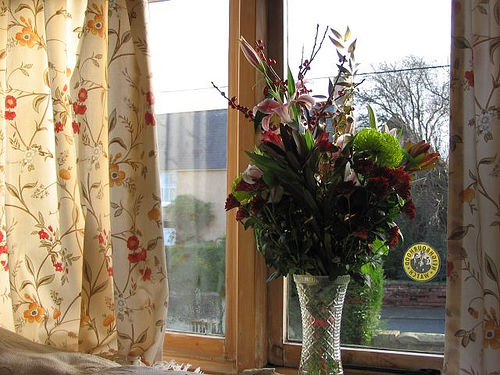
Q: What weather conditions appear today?
A: It is cloudy.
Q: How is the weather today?
A: It is cloudy.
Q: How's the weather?
A: It is cloudy.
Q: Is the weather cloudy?
A: Yes, it is cloudy.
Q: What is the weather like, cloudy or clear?
A: It is cloudy.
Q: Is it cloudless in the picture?
A: No, it is cloudy.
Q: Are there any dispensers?
A: No, there are no dispensers.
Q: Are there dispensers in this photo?
A: No, there are no dispensers.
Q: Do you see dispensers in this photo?
A: No, there are no dispensers.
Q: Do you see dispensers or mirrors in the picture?
A: No, there are no dispensers or mirrors.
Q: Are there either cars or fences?
A: No, there are no cars or fences.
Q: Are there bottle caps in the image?
A: No, there are no bottle caps.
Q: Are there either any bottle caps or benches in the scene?
A: No, there are no bottle caps or benches.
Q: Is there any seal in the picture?
A: Yes, there is a seal.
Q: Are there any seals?
A: Yes, there is a seal.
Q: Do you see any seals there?
A: Yes, there is a seal.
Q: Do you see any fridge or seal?
A: Yes, there is a seal.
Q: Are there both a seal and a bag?
A: No, there is a seal but no bags.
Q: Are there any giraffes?
A: No, there are no giraffes.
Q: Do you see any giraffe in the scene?
A: No, there are no giraffes.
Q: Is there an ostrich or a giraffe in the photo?
A: No, there are no giraffes or ostriches.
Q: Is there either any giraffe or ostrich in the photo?
A: No, there are no giraffes or ostriches.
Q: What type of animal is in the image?
A: The animal is a seal.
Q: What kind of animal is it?
A: The animal is a seal.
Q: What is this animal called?
A: This is a seal.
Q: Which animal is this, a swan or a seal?
A: This is a seal.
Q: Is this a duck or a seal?
A: This is a seal.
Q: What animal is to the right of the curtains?
A: The animal is a seal.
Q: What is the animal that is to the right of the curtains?
A: The animal is a seal.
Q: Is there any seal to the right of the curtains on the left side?
A: Yes, there is a seal to the right of the curtains.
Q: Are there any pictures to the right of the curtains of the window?
A: No, there is a seal to the right of the curtains.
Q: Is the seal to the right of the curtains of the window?
A: Yes, the seal is to the right of the curtains.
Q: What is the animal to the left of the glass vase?
A: The animal is a seal.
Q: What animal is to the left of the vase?
A: The animal is a seal.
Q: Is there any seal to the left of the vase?
A: Yes, there is a seal to the left of the vase.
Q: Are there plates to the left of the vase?
A: No, there is a seal to the left of the vase.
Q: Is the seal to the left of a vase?
A: Yes, the seal is to the left of a vase.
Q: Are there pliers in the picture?
A: No, there are no pliers.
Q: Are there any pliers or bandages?
A: No, there are no pliers or bandages.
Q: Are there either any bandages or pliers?
A: No, there are no pliers or bandages.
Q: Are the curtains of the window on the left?
A: Yes, the curtains are on the left of the image.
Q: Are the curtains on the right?
A: No, the curtains are on the left of the image.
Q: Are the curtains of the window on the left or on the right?
A: The curtains are on the left of the image.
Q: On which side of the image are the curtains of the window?
A: The curtains are on the left of the image.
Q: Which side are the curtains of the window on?
A: The curtains are on the left of the image.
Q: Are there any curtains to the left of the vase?
A: Yes, there are curtains to the left of the vase.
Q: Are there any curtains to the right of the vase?
A: No, the curtains are to the left of the vase.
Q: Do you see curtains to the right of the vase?
A: No, the curtains are to the left of the vase.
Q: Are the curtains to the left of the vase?
A: Yes, the curtains are to the left of the vase.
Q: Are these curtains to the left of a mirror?
A: No, the curtains are to the left of the vase.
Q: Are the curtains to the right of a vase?
A: No, the curtains are to the left of a vase.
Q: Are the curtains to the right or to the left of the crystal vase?
A: The curtains are to the left of the vase.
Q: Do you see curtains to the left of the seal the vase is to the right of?
A: Yes, there are curtains to the left of the seal.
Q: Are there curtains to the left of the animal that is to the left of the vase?
A: Yes, there are curtains to the left of the seal.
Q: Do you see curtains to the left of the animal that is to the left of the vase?
A: Yes, there are curtains to the left of the seal.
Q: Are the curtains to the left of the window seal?
A: Yes, the curtains are to the left of the seal.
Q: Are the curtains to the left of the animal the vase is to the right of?
A: Yes, the curtains are to the left of the seal.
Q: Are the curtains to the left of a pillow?
A: No, the curtains are to the left of the seal.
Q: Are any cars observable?
A: No, there are no cars.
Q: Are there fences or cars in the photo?
A: No, there are no cars or fences.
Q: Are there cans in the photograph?
A: No, there are no cans.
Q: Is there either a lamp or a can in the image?
A: No, there are no cans or lamps.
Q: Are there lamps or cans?
A: No, there are no cans or lamps.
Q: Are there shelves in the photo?
A: No, there are no shelves.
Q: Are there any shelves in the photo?
A: No, there are no shelves.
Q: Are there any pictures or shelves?
A: No, there are no shelves or pictures.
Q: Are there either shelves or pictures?
A: No, there are no shelves or pictures.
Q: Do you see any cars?
A: No, there are no cars.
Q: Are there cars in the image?
A: No, there are no cars.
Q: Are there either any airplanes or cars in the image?
A: No, there are no cars or airplanes.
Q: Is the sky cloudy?
A: Yes, the sky is cloudy.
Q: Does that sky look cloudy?
A: Yes, the sky is cloudy.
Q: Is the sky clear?
A: No, the sky is cloudy.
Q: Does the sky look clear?
A: No, the sky is cloudy.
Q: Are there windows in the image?
A: Yes, there is a window.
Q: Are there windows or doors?
A: Yes, there is a window.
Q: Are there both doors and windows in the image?
A: No, there is a window but no doors.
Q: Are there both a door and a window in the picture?
A: No, there is a window but no doors.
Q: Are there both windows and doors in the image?
A: No, there is a window but no doors.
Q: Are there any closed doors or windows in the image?
A: Yes, there is a closed window.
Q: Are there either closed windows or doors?
A: Yes, there is a closed window.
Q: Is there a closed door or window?
A: Yes, there is a closed window.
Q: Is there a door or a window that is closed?
A: Yes, the window is closed.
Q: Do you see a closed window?
A: Yes, there is a closed window.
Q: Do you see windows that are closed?
A: Yes, there is a window that is closed.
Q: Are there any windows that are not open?
A: Yes, there is an closed window.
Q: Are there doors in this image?
A: No, there are no doors.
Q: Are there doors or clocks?
A: No, there are no doors or clocks.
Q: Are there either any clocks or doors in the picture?
A: No, there are no doors or clocks.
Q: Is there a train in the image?
A: No, there are no trains.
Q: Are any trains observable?
A: No, there are no trains.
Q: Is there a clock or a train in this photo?
A: No, there are no trains or clocks.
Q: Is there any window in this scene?
A: Yes, there is a window.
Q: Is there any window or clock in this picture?
A: Yes, there is a window.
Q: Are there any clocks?
A: No, there are no clocks.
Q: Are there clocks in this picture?
A: No, there are no clocks.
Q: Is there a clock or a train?
A: No, there are no clocks or trains.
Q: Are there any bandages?
A: No, there are no bandages.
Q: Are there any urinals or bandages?
A: No, there are no bandages or urinals.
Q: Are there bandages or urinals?
A: No, there are no bandages or urinals.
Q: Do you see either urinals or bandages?
A: No, there are no bandages or urinals.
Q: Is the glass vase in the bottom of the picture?
A: Yes, the vase is in the bottom of the image.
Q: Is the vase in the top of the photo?
A: No, the vase is in the bottom of the image.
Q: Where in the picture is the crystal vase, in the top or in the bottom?
A: The vase is in the bottom of the image.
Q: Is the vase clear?
A: Yes, the vase is clear.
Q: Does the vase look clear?
A: Yes, the vase is clear.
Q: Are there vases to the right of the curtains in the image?
A: Yes, there is a vase to the right of the curtains.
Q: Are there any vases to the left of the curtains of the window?
A: No, the vase is to the right of the curtains.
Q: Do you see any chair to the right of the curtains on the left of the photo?
A: No, there is a vase to the right of the curtains.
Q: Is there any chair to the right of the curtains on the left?
A: No, there is a vase to the right of the curtains.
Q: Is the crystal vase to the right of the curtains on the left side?
A: Yes, the vase is to the right of the curtains.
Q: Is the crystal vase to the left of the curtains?
A: No, the vase is to the right of the curtains.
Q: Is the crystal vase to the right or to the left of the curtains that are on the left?
A: The vase is to the right of the curtains.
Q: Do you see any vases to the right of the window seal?
A: Yes, there is a vase to the right of the seal.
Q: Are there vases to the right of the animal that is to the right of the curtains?
A: Yes, there is a vase to the right of the seal.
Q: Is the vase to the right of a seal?
A: Yes, the vase is to the right of a seal.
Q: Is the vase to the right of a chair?
A: No, the vase is to the right of a seal.